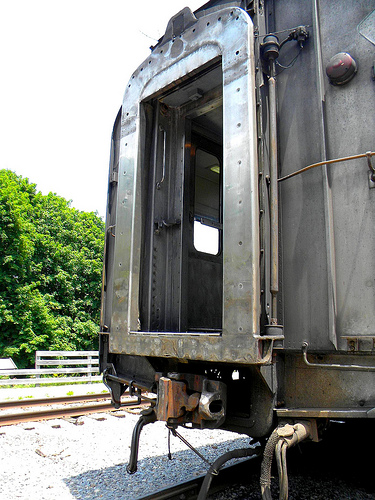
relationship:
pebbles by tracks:
[1, 407, 274, 499] [1, 393, 261, 500]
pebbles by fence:
[10, 385, 69, 398] [1, 346, 101, 386]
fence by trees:
[1, 346, 101, 386] [0, 168, 108, 380]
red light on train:
[321, 47, 365, 91] [98, 0, 375, 497]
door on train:
[140, 54, 228, 337] [98, 0, 375, 497]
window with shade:
[194, 149, 221, 256] [191, 151, 226, 228]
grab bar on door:
[154, 120, 170, 195] [140, 54, 228, 337]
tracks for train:
[1, 393, 261, 500] [98, 0, 375, 497]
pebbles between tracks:
[1, 407, 274, 499] [1, 393, 261, 500]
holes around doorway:
[114, 12, 257, 83] [92, 6, 271, 370]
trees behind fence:
[0, 168, 108, 380] [1, 346, 101, 386]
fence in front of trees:
[1, 346, 101, 386] [0, 168, 108, 380]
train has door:
[98, 0, 375, 497] [140, 54, 228, 337]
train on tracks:
[98, 0, 375, 497] [1, 393, 261, 500]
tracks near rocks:
[1, 393, 261, 500] [77, 480, 133, 498]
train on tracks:
[98, 2, 355, 496] [1, 393, 261, 500]